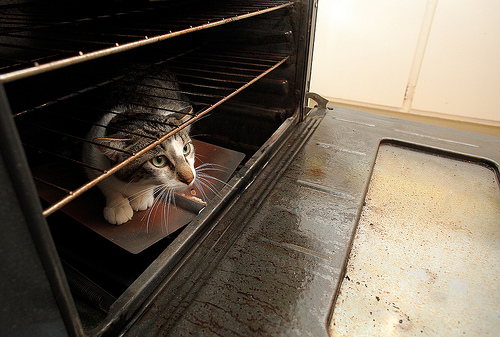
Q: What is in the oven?
A: The kitty.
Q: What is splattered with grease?
A: Oven window.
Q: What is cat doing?
A: Hiding in turned off oven.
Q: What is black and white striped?
A: A cat.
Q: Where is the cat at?
A: In oven.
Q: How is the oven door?
A: Dirty.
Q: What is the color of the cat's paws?
A: White.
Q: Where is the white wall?
A: Behind the oven.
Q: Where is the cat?
A: In the oven.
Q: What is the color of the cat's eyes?
A: Green.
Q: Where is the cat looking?
A: Outside the oven.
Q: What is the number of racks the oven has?
A: Three.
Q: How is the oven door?
A: Open.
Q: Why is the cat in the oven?
A: Hiding.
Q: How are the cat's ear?
A: Back.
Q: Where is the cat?
A: Oven.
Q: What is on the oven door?
A: Grease.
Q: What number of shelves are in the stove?
A: 2.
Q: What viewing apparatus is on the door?
A: Window.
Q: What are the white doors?
A: Cabinets.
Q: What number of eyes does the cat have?
A: 2.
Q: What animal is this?
A: Cat.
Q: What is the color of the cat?
A: White, grey and black.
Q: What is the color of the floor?
A: Brown.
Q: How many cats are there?
A: One.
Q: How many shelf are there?
A: Two.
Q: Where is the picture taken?
A: In the kitchen.